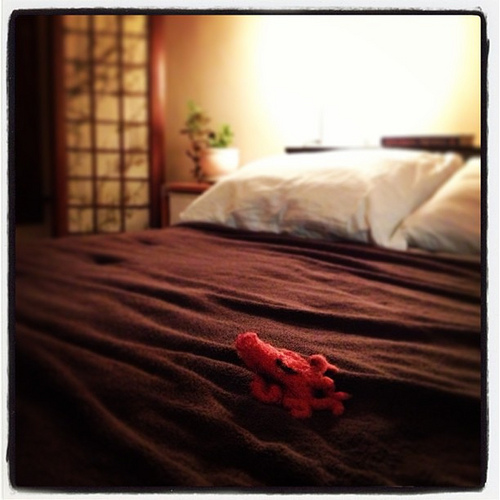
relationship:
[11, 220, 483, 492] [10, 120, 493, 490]
covers on bed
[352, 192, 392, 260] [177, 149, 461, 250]
wrinkle on pillow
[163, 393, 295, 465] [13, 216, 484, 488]
wrinkle on cover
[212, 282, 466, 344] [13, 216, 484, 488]
wrinkle on cover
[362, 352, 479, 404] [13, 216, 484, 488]
wrinkle on cover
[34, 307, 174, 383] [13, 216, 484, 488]
wrinkle on cover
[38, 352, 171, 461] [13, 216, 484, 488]
wrinkle on cover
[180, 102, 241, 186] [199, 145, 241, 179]
plant in a white pot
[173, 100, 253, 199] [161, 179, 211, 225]
plant on table